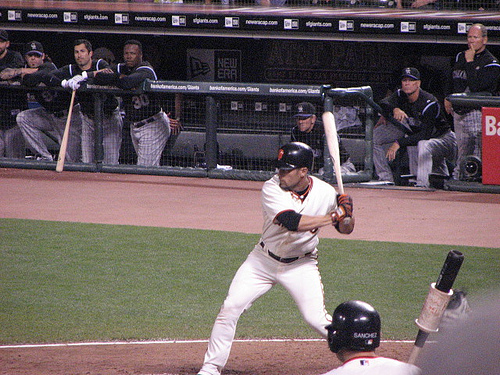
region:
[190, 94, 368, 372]
a baseball player wearing white cloths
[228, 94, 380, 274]
baseball player holding a bat with two hans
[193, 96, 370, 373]
baseball player in position to hit a ball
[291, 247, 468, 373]
a baseball player holding a black bat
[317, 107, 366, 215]
wood bat is brown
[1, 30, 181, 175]
baseball player waiting in the dugout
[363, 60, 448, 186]
old man is sit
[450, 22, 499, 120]
a man with left hand in mouth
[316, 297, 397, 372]
black helmet to play baseball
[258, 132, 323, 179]
black helmet with a red ornament in front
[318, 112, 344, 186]
the bat is white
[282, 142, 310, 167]
the helmet is black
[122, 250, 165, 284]
the grass is green in color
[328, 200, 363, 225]
the gloves are orange and black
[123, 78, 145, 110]
the jersey is black and white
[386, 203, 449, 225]
the dirt is brown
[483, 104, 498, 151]
the sign is red and white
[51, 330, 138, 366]
the line is white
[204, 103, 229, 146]
the pole is black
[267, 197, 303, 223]
the jersey is white and orange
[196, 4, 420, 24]
roof of players' dugout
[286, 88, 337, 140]
player sitting in dugout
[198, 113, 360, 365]
player with bat in hand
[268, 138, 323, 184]
black helmet on head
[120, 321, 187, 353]
white line on field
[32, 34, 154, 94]
players leaning over railing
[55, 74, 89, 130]
bat in gloved hands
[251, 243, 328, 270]
black belt on uniform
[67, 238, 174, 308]
green grass of baseball field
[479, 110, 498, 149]
white letter on red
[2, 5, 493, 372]
Men playing baseball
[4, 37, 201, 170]
The batter's opposing team in the dugout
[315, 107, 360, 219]
A wooden baseball bat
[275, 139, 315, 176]
A black helmet on the man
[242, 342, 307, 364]
Dirt beneath the batter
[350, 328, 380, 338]
The helmet says "Sanchez"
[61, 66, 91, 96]
White gloves on the man's hands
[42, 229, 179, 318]
The grass is very short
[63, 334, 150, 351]
White line son the ground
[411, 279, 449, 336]
Weight trainer on the bat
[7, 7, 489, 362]
a baseball game in progress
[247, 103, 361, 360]
batter ready to swing at the ball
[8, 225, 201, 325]
green grass on the baseball field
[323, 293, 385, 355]
black protective baseball helmet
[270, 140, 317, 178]
black baseball helmet with orange logo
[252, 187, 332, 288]
white baseball uniform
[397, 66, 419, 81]
dark blue and white baseball cap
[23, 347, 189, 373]
brown dirt in the baseball diamond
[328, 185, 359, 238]
orange and black athletic gloves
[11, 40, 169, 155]
opposing team members watching the batter